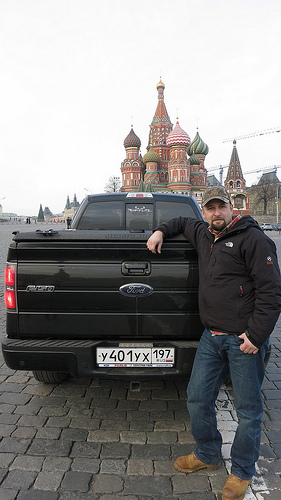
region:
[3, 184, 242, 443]
the truck is black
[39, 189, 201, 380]
the truck is black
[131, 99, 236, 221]
the castle is colorful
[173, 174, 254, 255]
A man in a camoflage cap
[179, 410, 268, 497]
Work boots and blue jeans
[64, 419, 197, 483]
Gray cobblestone beneath work boots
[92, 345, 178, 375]
License plate from another country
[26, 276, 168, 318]
A black Ford F150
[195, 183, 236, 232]
Man in a camo cap with a goatee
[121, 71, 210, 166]
Building roofs are very colorful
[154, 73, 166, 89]
The top is gold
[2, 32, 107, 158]
The sky is white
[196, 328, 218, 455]
Blue denim jeans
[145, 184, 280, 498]
a man standing behind a truck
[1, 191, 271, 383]
a large, black pickup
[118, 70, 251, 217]
a Russian-looking castle behind the truck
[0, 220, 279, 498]
a large, stone-paved area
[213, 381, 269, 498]
a white line on the stones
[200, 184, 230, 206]
a camouflage hat on the man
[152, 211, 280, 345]
a black coat on the man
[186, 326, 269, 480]
blue jeans on the man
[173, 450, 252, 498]
work boots on the man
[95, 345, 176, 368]
license plate on the truck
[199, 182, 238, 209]
man is wearing a hat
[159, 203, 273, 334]
man's jacket is black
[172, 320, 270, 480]
man wearing blue jeans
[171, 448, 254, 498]
man's shoes are brown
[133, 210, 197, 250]
man's arm on truck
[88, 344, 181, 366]
white license plate on truck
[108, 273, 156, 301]
blue logo on truck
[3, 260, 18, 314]
truck has red tail lights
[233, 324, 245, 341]
man's finger in pocket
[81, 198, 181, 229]
truck's windows are black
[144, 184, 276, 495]
the man standing behind the truck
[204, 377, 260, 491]
the white line on the ground near the man's feet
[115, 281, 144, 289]
the Ford logo on the back of the truck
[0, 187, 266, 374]
the parked black truck the man is leaning on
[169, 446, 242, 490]
the brown shoes on the man's feet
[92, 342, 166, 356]
the license plate on the back of the truck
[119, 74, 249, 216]
the large colorful building behind the man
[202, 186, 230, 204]
the hat on the man's head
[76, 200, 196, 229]
the window on the back of the truck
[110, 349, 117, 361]
the 4 on the license plate